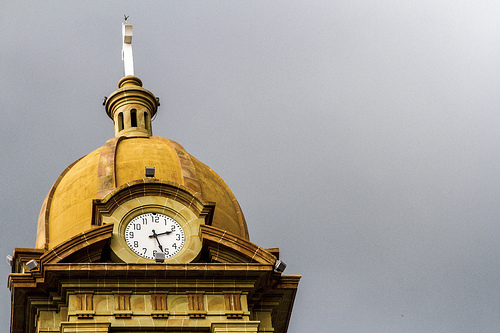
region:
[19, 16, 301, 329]
the dome is yellow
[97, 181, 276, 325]
a clock under an arch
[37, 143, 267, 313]
the clock face is white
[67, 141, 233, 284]
the clock has black arrows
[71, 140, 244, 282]
the numbers are black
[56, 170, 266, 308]
the numbers are latin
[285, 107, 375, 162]
the sky is overcast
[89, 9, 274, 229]
a cross at the top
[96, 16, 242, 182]
the cross is white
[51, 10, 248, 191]
the cross on top of the cupola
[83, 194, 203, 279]
A clock on a tower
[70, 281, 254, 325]
Small columns on the side of a building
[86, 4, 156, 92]
A cross on the top of a tower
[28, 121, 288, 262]
A domed top to a building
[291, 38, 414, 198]
A section of gray sky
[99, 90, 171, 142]
A windowed room at the top of a tower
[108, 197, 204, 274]
A clock showing 2:27 as the time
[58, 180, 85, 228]
A yellow section of a tower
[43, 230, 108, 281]
An arch element in a tower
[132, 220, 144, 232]
A 10 from a clock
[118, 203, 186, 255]
clock on large building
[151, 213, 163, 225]
number on clock face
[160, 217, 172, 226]
number on clock face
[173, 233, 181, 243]
number on clock face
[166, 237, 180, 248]
number on clock face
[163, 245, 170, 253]
number on clock face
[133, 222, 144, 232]
number on clock face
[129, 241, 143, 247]
number on clock face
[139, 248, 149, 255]
number on clock face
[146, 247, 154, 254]
number on clock face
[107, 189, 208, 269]
analog clock that says two twenty-seven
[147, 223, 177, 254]
analog clock hands for hour and minute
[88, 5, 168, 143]
side view of a cross on tower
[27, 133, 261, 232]
dome of a tower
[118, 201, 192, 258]
clock face with hour and minute markings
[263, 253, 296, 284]
security light on corner of building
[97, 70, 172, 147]
three windows in tower top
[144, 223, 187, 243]
clock hour hand pointing to two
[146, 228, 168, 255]
black analog clock minute hand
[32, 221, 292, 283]
stone arch on clock tower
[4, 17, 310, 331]
large yellow cathedral roof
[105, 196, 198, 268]
white and black clock face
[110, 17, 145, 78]
large white stone cross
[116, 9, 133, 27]
little black bird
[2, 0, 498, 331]
vast area of hazy gray sky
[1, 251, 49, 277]
gray lights to illuminate cross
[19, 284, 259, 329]
beautiful stone work on cathedral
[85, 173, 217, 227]
stone arch over clock face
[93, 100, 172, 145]
small windows on top of cathedral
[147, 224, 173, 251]
two black clock hands